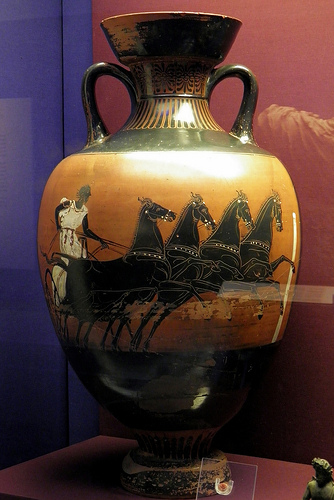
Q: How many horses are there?
A: Four.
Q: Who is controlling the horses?
A: The person in white clothes.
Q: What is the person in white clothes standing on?
A: Chariot.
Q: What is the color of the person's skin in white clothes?
A: Black.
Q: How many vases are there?
A: One.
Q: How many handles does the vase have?
A: Two.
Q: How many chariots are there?
A: One.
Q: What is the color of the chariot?
A: Black.